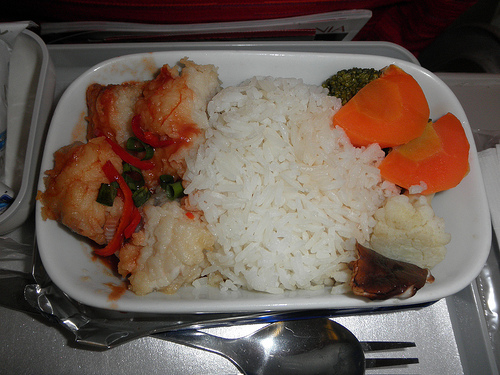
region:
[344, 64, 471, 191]
Pieces of carrot on plate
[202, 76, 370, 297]
Ball of white rice on plate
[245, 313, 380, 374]
Top of silver spoon near plate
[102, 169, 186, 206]
Green sliced onions on plate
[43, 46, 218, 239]
Sweet and sour chicken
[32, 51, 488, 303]
Rectangular white plate with food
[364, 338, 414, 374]
Fork tines under spoon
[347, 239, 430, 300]
Bit of food on edge of plate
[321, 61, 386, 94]
Broccoli under carrots on plate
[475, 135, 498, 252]
Edge of napkin beside plate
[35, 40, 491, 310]
the meal is served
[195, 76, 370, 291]
rice is on the dish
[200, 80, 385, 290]
the rice is white in color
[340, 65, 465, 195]
the carrots are sliced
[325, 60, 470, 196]
the carrots are orange in color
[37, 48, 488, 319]
the dish is white in color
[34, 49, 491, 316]
the dish is made of ceramic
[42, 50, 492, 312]
the dish is shiny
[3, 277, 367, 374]
the spoon is made of metal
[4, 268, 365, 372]
the spoon is shiny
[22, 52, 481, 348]
the plate is white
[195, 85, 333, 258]
the rice is white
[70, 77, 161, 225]
the flavoring is orange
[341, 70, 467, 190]
this food is orange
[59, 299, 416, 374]
utensils next to the plate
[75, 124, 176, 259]
peppers in the food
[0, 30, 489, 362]
the plate is on a tray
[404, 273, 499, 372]
the tray is silver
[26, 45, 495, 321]
a compact meal served on an airplane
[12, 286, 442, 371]
silverware accompanies the meal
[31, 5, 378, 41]
a magazine in the rack behind the forward seat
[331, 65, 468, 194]
sliced steamed carrots are part of the meal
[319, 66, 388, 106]
broccoli floret is a part of this meal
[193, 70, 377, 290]
white rice is served in the center of the plate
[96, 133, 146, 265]
sliced red peppers are an ingredient of this meal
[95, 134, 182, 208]
sliced green onions are an ingredient of this meal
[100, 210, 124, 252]
sliced onion is an ingredient of this meal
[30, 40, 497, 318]
the serving plate is oblong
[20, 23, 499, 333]
this is a plate of food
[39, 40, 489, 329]
this is a hot meal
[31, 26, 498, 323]
this is a meal on an airplane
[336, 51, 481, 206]
cooked vegetables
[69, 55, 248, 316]
cooked pieces of fish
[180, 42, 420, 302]
some steamed white rice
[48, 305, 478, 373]
metal eating utensils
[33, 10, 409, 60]
a magazine in a seat-back pocket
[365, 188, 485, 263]
a piece of cauliflower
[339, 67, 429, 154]
a slice of carrot on a plate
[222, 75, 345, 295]
white rice on a plate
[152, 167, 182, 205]
cut green onion on a plate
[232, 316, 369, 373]
a silver spoon on a tray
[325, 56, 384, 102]
a piece of broccoli on plate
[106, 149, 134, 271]
cut red pepper on a plate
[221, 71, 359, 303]
cooked rice on a plate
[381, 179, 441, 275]
cooked cauliflower on a plate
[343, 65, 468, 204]
cooked carrots on a plate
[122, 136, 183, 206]
cooked onions on a plate